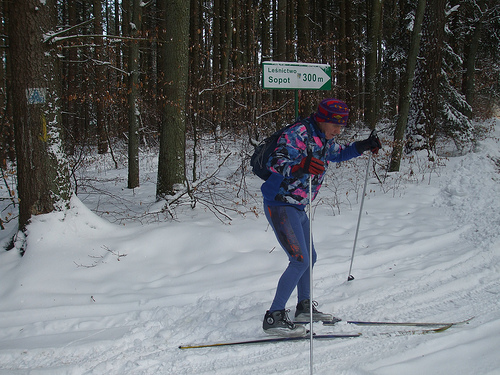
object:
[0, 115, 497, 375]
snow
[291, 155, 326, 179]
glove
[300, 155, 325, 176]
hand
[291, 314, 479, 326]
skis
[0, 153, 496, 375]
hill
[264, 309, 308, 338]
man's feet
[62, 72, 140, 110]
leaves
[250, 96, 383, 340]
man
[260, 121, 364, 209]
jacket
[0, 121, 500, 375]
ground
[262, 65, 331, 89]
arrow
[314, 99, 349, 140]
hat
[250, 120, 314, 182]
backpack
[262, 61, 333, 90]
sign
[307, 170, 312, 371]
pole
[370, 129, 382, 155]
glove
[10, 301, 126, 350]
tracks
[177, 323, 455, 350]
skis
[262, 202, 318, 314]
pants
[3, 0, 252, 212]
trees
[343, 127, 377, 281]
poles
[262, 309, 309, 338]
shoes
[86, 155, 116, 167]
leaves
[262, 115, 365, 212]
sweater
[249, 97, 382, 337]
lady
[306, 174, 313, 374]
stick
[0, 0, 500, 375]
picture